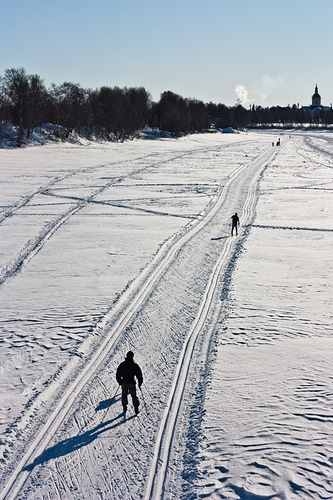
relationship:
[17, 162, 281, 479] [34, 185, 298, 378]
tracks in snow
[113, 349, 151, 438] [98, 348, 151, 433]
man on skiing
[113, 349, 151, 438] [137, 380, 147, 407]
man has pole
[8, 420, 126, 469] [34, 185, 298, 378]
shadow on snow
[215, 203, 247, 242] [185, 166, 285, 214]
man in front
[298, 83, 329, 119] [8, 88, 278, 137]
building behind trees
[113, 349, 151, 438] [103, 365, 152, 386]
man wearing jacket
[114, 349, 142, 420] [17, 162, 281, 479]
man on tracks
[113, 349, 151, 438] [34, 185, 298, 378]
man in snow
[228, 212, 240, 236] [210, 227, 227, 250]
man has shadow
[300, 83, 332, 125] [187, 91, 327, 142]
building in distance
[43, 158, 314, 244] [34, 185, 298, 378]
ridges in snow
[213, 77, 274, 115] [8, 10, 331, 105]
smoke in sky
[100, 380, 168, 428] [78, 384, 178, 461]
pole for skiing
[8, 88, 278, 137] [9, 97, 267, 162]
trees in a cluster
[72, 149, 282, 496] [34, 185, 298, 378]
roadway in snow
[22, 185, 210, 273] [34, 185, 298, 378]
ripples in snow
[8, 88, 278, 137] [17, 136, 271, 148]
trees in a line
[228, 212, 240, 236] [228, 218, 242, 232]
man wearing clothing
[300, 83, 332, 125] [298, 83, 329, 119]
building like building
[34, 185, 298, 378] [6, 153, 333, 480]
snow covered field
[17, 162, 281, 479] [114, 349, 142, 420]
tracks from man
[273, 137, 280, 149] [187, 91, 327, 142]
people in distance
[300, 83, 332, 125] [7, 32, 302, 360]
building in winter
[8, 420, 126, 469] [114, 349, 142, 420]
shadow of man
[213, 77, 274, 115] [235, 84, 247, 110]
smoke in pillar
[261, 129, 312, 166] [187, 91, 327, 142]
people in distance